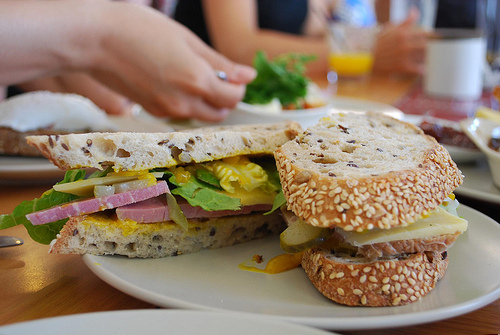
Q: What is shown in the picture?
A: A sandwich.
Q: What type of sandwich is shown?
A: Ham and cheese.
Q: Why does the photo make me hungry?
A: The sandwich looks tasty.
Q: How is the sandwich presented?
A: Cut in two on a plate.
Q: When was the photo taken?
A: Daytime.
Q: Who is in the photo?
A: Three ladies.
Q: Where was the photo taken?
A: Indoors at a restaurant.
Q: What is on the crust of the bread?
A: Sesame seeds.